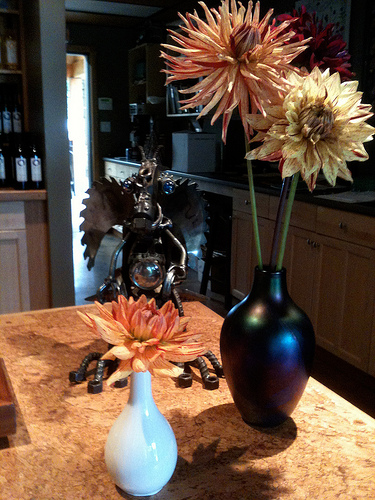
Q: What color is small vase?
A: White.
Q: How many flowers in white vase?
A: One.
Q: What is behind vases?
A: Statue.